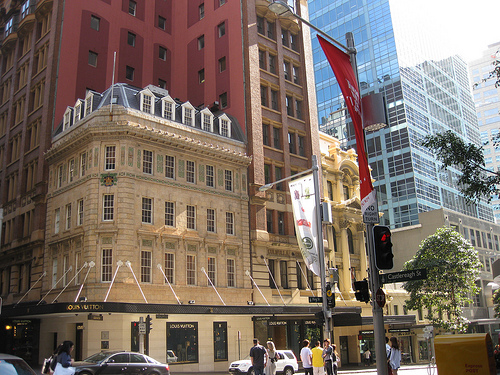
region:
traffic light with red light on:
[367, 222, 397, 273]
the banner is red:
[306, 33, 386, 154]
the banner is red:
[261, 26, 458, 293]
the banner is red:
[278, 52, 409, 249]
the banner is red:
[264, 3, 374, 216]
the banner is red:
[315, 96, 379, 324]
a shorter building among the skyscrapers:
[49, 84, 246, 373]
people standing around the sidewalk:
[297, 337, 342, 372]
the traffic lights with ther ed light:
[369, 223, 399, 273]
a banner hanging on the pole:
[278, 162, 323, 279]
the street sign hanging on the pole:
[378, 266, 423, 283]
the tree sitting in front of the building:
[403, 223, 480, 334]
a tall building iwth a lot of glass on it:
[311, 0, 483, 242]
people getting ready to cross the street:
[245, 337, 276, 370]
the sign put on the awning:
[56, 297, 101, 314]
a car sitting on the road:
[77, 343, 167, 373]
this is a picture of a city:
[40, 95, 460, 362]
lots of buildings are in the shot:
[9, 10, 487, 295]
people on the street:
[168, 284, 435, 374]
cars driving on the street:
[5, 338, 295, 374]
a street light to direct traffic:
[323, 182, 426, 362]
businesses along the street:
[25, 281, 415, 371]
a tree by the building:
[362, 222, 491, 364]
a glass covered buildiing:
[303, 5, 498, 252]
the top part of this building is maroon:
[23, 2, 278, 207]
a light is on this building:
[1, 297, 37, 373]